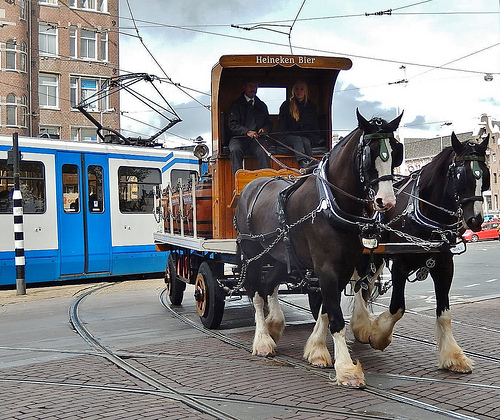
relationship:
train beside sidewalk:
[0, 107, 210, 281] [1, 278, 482, 418]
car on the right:
[464, 230, 483, 238] [273, 13, 484, 407]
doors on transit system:
[59, 153, 127, 280] [3, 115, 157, 293]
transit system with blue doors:
[3, 115, 157, 293] [59, 153, 127, 280]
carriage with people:
[151, 40, 496, 392] [275, 79, 322, 168]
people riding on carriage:
[275, 79, 322, 168] [151, 40, 496, 392]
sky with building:
[173, 20, 218, 61] [0, 2, 129, 131]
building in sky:
[0, 2, 129, 131] [173, 20, 218, 61]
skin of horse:
[320, 237, 343, 256] [215, 114, 407, 396]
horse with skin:
[215, 114, 407, 396] [320, 237, 343, 256]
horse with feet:
[215, 114, 407, 396] [248, 310, 377, 399]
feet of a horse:
[248, 310, 377, 399] [215, 114, 407, 396]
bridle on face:
[358, 172, 397, 226] [350, 117, 405, 217]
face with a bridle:
[350, 117, 405, 217] [358, 172, 397, 226]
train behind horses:
[0, 107, 210, 281] [361, 129, 493, 374]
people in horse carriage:
[227, 70, 323, 169] [202, 44, 353, 241]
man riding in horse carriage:
[219, 63, 281, 165] [225, 70, 324, 180]